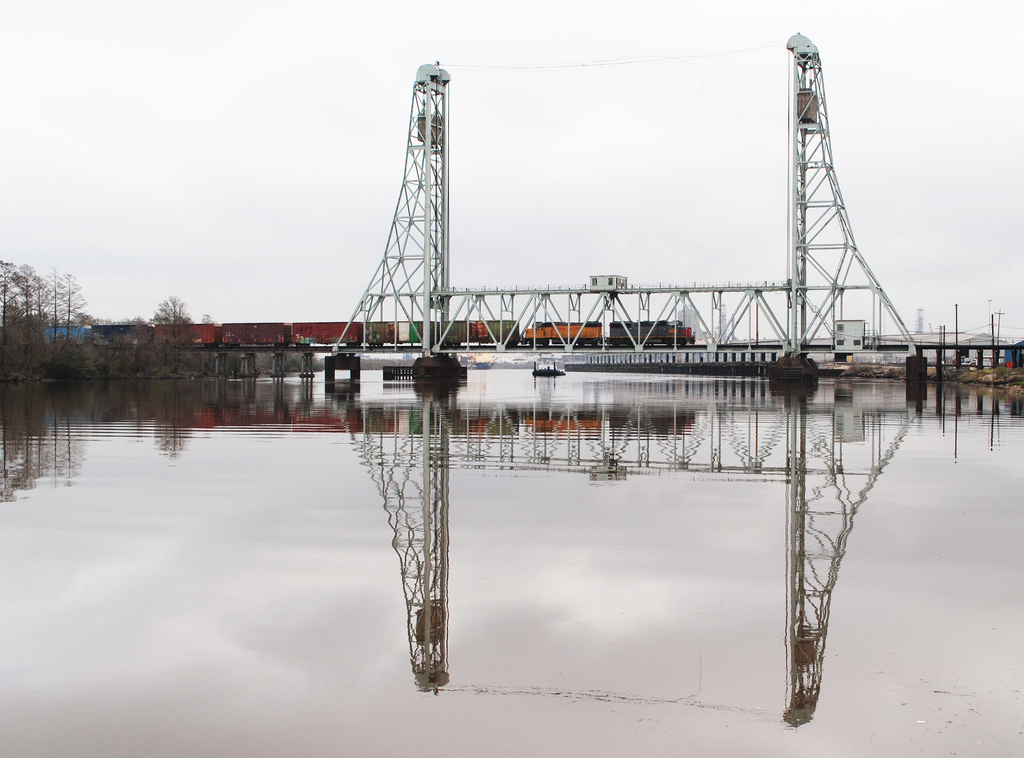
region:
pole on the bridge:
[873, 275, 889, 339]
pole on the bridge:
[699, 329, 732, 367]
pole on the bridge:
[422, 309, 442, 348]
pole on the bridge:
[936, 275, 971, 339]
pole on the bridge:
[362, 309, 375, 335]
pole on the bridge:
[380, 220, 441, 268]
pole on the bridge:
[804, 180, 837, 209]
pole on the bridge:
[392, 139, 459, 194]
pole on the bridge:
[580, 294, 680, 343]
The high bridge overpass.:
[344, 36, 923, 363]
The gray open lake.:
[3, 378, 1022, 755]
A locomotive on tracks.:
[38, 319, 694, 346]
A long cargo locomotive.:
[46, 321, 701, 344]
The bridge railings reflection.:
[338, 376, 923, 721]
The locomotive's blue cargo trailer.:
[52, 324, 87, 340]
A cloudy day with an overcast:
[0, 0, 1021, 343]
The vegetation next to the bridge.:
[0, 264, 294, 381]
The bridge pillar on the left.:
[352, 59, 463, 344]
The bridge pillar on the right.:
[779, 29, 915, 355]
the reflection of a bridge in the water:
[325, 399, 905, 732]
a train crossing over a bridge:
[35, 310, 707, 356]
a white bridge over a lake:
[319, 47, 943, 386]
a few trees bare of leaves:
[0, 250, 109, 383]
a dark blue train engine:
[594, 310, 711, 361]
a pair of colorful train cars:
[215, 309, 359, 352]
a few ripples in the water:
[62, 402, 200, 459]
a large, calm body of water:
[24, 260, 1005, 751]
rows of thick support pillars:
[205, 342, 324, 387]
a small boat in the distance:
[512, 347, 574, 402]